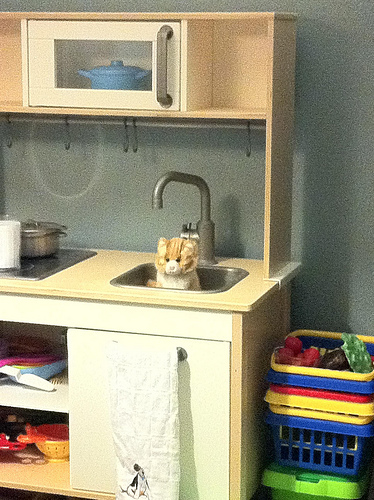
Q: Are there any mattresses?
A: No, there are no mattresses.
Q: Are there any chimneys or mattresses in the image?
A: No, there are no mattresses or chimneys.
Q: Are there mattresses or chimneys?
A: No, there are no mattresses or chimneys.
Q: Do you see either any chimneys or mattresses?
A: No, there are no mattresses or chimneys.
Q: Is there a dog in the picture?
A: Yes, there is a dog.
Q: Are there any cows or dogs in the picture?
A: Yes, there is a dog.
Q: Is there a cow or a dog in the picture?
A: Yes, there is a dog.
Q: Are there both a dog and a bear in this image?
A: No, there is a dog but no bears.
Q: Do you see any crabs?
A: No, there are no crabs.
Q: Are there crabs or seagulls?
A: No, there are no crabs or seagulls.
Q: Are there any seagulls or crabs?
A: No, there are no crabs or seagulls.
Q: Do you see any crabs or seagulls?
A: No, there are no crabs or seagulls.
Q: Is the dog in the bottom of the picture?
A: Yes, the dog is in the bottom of the image.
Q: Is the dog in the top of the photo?
A: No, the dog is in the bottom of the image.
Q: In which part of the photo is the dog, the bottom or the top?
A: The dog is in the bottom of the image.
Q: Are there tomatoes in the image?
A: Yes, there are tomatoes.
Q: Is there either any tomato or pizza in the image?
A: Yes, there are tomatoes.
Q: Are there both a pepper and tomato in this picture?
A: No, there are tomatoes but no peppers.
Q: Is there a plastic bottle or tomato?
A: Yes, there are plastic tomatoes.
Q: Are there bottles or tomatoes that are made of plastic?
A: Yes, the tomatoes are made of plastic.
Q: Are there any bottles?
A: No, there are no bottles.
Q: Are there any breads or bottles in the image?
A: No, there are no bottles or breads.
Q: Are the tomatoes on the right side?
A: Yes, the tomatoes are on the right of the image.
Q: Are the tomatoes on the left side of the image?
A: No, the tomatoes are on the right of the image.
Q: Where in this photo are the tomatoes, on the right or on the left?
A: The tomatoes are on the right of the image.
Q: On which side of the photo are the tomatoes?
A: The tomatoes are on the right of the image.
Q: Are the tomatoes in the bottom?
A: Yes, the tomatoes are in the bottom of the image.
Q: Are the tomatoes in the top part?
A: No, the tomatoes are in the bottom of the image.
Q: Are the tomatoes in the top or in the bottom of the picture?
A: The tomatoes are in the bottom of the image.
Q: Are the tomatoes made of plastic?
A: Yes, the tomatoes are made of plastic.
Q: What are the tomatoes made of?
A: The tomatoes are made of plastic.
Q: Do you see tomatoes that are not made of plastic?
A: No, there are tomatoes but they are made of plastic.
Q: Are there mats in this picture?
A: No, there are no mats.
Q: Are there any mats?
A: No, there are no mats.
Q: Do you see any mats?
A: No, there are no mats.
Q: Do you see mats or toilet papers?
A: No, there are no mats or toilet papers.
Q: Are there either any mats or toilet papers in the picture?
A: No, there are no mats or toilet papers.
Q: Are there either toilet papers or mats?
A: No, there are no mats or toilet papers.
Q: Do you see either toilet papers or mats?
A: No, there are no mats or toilet papers.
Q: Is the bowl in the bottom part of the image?
A: No, the bowl is in the top of the image.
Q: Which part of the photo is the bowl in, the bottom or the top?
A: The bowl is in the top of the image.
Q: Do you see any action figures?
A: No, there are no action figures.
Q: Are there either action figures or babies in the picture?
A: No, there are no action figures or babies.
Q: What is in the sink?
A: The stuffed animal is in the sink.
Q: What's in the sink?
A: The stuffed animal is in the sink.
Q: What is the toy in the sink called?
A: The toy is a stuffed animal.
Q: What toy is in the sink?
A: The toy is a stuffed animal.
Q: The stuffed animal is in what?
A: The stuffed animal is in the sink.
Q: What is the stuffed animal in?
A: The stuffed animal is in the sink.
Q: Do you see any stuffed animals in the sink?
A: Yes, there is a stuffed animal in the sink.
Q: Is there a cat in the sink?
A: No, there is a stuffed animal in the sink.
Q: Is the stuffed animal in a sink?
A: Yes, the stuffed animal is in a sink.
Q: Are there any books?
A: No, there are no books.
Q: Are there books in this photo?
A: No, there are no books.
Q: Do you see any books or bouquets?
A: No, there are no books or bouquets.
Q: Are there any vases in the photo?
A: No, there are no vases.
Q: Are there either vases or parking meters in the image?
A: No, there are no vases or parking meters.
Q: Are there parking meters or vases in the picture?
A: No, there are no vases or parking meters.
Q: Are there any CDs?
A: No, there are no cds.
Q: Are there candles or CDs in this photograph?
A: No, there are no CDs or candles.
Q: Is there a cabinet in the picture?
A: Yes, there is a cabinet.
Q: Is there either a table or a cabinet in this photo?
A: Yes, there is a cabinet.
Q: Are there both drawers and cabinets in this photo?
A: No, there is a cabinet but no drawers.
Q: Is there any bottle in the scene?
A: No, there are no bottles.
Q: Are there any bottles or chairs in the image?
A: No, there are no bottles or chairs.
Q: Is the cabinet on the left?
A: Yes, the cabinet is on the left of the image.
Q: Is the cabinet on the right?
A: No, the cabinet is on the left of the image.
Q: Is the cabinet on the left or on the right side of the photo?
A: The cabinet is on the left of the image.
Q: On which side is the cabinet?
A: The cabinet is on the left of the image.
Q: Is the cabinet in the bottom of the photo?
A: Yes, the cabinet is in the bottom of the image.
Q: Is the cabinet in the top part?
A: No, the cabinet is in the bottom of the image.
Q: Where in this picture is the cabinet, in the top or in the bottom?
A: The cabinet is in the bottom of the image.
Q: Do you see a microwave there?
A: Yes, there is a microwave.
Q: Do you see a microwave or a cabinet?
A: Yes, there is a microwave.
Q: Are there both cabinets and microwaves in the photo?
A: Yes, there are both a microwave and a cabinet.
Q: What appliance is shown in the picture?
A: The appliance is a microwave.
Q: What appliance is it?
A: The appliance is a microwave.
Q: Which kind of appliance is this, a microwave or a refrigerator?
A: That is a microwave.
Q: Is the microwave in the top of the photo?
A: Yes, the microwave is in the top of the image.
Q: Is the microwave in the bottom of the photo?
A: No, the microwave is in the top of the image.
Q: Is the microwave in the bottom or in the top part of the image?
A: The microwave is in the top of the image.